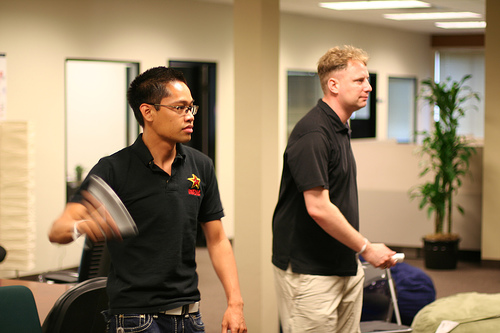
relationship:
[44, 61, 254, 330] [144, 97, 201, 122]
man wearing glasses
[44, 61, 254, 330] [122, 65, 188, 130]
man has hair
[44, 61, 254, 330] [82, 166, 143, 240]
man holding wii remote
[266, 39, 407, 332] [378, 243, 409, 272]
man holding wii remote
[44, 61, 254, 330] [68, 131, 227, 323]
man wearing shirt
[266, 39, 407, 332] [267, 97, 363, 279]
man wearing shirt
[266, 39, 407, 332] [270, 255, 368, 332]
man wearing pants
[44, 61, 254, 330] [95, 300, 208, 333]
man wearing jeans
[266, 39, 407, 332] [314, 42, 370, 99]
man has hair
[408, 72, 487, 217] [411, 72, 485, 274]
leaves are on plant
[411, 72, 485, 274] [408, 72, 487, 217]
plant has leaves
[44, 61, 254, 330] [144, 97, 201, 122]
man has glasses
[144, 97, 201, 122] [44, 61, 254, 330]
glasses are on man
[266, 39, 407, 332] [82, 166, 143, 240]
man holding wii remote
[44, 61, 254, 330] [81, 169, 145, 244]
man playing game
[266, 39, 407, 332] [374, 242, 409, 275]
man playing game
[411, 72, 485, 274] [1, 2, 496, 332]
plant in photo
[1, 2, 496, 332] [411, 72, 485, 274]
photo has plant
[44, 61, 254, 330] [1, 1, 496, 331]
man in room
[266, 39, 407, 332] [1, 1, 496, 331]
man in room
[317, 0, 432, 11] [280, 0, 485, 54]
light are on ceiling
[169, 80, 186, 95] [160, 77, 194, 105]
light on forehead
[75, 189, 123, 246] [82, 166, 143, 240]
hand has wii remote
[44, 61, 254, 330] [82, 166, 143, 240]
man playing with wii remote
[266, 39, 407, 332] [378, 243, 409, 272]
man playing with wii remote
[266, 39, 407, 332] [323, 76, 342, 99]
man has ear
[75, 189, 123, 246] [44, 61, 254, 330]
hand on man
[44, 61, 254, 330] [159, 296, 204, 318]
man has belt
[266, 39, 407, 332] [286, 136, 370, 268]
man has arm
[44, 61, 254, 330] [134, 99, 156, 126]
man has ear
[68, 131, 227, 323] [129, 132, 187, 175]
shirt has collar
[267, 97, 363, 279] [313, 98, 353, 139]
shirt has collar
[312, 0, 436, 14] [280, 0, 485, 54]
light on ceiling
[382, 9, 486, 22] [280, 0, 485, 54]
light on ceiling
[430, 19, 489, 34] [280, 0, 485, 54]
light on ceiling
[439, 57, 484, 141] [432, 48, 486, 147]
mini blinds over window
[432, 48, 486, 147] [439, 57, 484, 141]
window has mini blinds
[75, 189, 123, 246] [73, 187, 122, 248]
hand in motion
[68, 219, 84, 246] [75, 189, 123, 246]
bangle on hand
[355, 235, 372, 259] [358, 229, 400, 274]
bangle on hand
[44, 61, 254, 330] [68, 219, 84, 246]
man has bangle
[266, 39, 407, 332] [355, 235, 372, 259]
man has bangle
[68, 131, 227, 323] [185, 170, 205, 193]
shirt has star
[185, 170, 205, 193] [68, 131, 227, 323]
star on shirt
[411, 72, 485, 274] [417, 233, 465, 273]
plant inside vase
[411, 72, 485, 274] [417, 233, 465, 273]
plant in vase